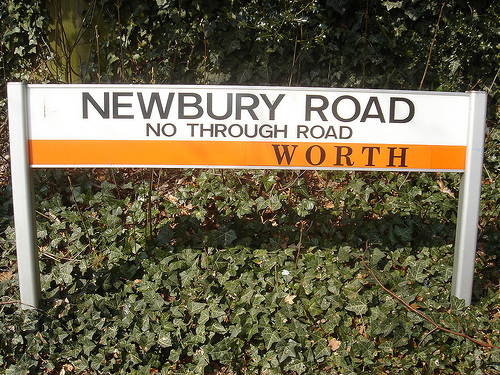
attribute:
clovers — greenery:
[193, 234, 348, 320]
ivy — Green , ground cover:
[0, 124, 499, 373]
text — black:
[75, 90, 418, 179]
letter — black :
[270, 144, 296, 165]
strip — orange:
[31, 138, 463, 175]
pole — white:
[6, 75, 48, 322]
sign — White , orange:
[21, 74, 483, 174]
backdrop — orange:
[27, 138, 467, 170]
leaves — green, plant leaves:
[26, 180, 473, 367]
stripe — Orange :
[28, 139, 465, 171]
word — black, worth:
[270, 140, 407, 169]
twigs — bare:
[361, 254, 490, 356]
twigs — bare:
[286, 208, 315, 270]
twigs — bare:
[137, 195, 162, 252]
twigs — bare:
[150, 167, 167, 193]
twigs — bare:
[63, 171, 89, 240]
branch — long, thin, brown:
[367, 265, 497, 348]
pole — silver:
[426, 79, 487, 315]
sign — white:
[3, 77, 485, 207]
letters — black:
[79, 86, 109, 121]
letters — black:
[112, 86, 135, 118]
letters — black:
[134, 88, 174, 122]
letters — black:
[173, 86, 205, 118]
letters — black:
[205, 90, 236, 120]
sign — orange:
[1, 69, 495, 342]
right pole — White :
[450, 85, 487, 309]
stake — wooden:
[5, 70, 45, 316]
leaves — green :
[0, 173, 500, 372]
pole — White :
[4, 80, 37, 330]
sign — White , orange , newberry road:
[4, 78, 492, 317]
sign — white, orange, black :
[10, 60, 482, 195]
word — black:
[263, 138, 415, 175]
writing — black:
[81, 93, 414, 166]